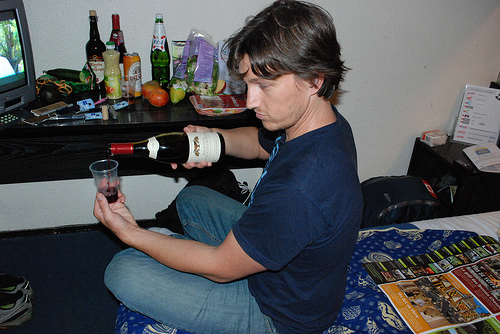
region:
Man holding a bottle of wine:
[87, 0, 359, 331]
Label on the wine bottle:
[187, 131, 221, 162]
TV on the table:
[1, 3, 37, 110]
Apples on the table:
[141, 78, 168, 106]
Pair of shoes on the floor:
[1, 269, 33, 331]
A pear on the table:
[168, 83, 184, 102]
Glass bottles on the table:
[84, 6, 171, 85]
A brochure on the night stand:
[462, 140, 498, 170]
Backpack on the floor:
[358, 171, 455, 223]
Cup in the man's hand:
[89, 157, 122, 202]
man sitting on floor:
[18, 8, 387, 327]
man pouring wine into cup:
[46, 110, 268, 245]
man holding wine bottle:
[93, 130, 245, 172]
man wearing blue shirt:
[218, 0, 388, 332]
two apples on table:
[135, 67, 179, 114]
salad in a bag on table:
[173, 2, 256, 115]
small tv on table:
[3, 4, 45, 128]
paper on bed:
[359, 240, 497, 330]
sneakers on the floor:
[0, 256, 45, 332]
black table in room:
[21, 91, 371, 189]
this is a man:
[226, 28, 341, 306]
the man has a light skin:
[158, 242, 215, 273]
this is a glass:
[93, 164, 117, 182]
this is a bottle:
[143, 133, 211, 159]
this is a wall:
[359, 0, 451, 102]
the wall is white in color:
[376, 28, 418, 100]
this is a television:
[3, 11, 29, 101]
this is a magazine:
[411, 256, 496, 322]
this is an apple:
[143, 87, 168, 105]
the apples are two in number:
[141, 75, 164, 102]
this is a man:
[197, 0, 360, 317]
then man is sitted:
[186, 33, 348, 332]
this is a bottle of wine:
[124, 127, 216, 172]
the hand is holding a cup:
[92, 157, 124, 193]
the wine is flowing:
[105, 150, 112, 165]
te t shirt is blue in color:
[283, 162, 331, 236]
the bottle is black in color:
[169, 140, 183, 156]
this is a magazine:
[410, 260, 495, 304]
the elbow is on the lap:
[180, 241, 236, 288]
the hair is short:
[273, 43, 294, 70]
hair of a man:
[293, 24, 341, 74]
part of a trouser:
[172, 275, 202, 307]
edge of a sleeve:
[228, 225, 250, 260]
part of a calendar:
[391, 256, 419, 307]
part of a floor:
[63, 274, 88, 303]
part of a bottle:
[161, 132, 180, 154]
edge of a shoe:
[143, 310, 163, 332]